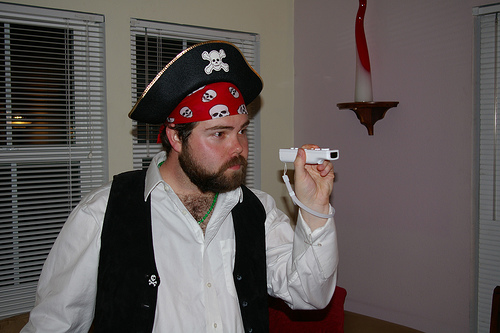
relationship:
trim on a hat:
[126, 38, 261, 116] [124, 41, 264, 127]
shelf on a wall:
[338, 97, 401, 137] [292, 13, 474, 330]